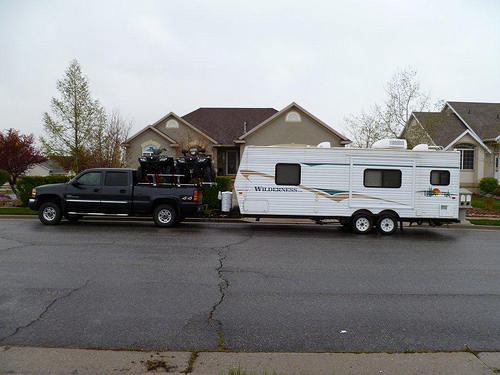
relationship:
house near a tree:
[123, 102, 345, 220] [45, 58, 117, 173]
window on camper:
[273, 161, 301, 186] [233, 145, 461, 235]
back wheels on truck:
[135, 195, 236, 255] [26, 165, 203, 231]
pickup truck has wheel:
[29, 168, 218, 227] [36, 197, 62, 226]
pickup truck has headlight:
[29, 168, 218, 227] [29, 183, 38, 201]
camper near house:
[227, 135, 468, 236] [112, 98, 356, 187]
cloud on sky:
[0, 0, 500, 158] [2, 0, 498, 165]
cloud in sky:
[0, 0, 500, 158] [28, 14, 489, 102]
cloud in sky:
[307, 19, 494, 147] [28, 14, 489, 102]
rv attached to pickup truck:
[234, 138, 460, 233] [29, 168, 218, 227]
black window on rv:
[359, 165, 404, 192] [231, 135, 464, 240]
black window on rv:
[426, 162, 453, 187] [231, 135, 464, 240]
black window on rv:
[271, 158, 303, 186] [231, 135, 464, 240]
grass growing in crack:
[177, 351, 206, 374] [180, 347, 199, 374]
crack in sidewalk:
[180, 347, 199, 374] [10, 340, 499, 374]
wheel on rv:
[352, 213, 373, 234] [226, 131, 468, 236]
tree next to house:
[44, 55, 111, 187] [112, 81, 353, 197]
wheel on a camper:
[353, 212, 371, 238] [233, 145, 461, 235]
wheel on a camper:
[380, 210, 399, 235] [233, 145, 461, 235]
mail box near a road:
[449, 176, 491, 244] [0, 219, 498, 351]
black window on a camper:
[363, 168, 402, 188] [233, 145, 461, 235]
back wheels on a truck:
[153, 204, 177, 228] [38, 171, 204, 224]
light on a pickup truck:
[194, 190, 203, 203] [35, 167, 211, 230]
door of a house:
[224, 148, 239, 176] [116, 98, 353, 170]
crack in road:
[190, 217, 257, 362] [1, 207, 495, 357]